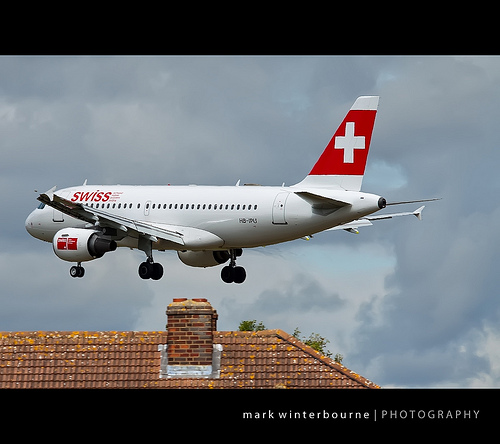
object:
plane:
[25, 95, 442, 282]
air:
[13, 60, 128, 140]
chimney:
[166, 297, 219, 379]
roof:
[1, 330, 382, 389]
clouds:
[0, 56, 499, 388]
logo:
[71, 188, 113, 202]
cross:
[334, 122, 365, 164]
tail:
[293, 95, 378, 192]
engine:
[52, 226, 118, 261]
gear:
[220, 248, 247, 282]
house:
[0, 298, 384, 390]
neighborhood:
[0, 297, 383, 388]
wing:
[294, 190, 351, 206]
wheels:
[138, 262, 152, 281]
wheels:
[219, 265, 238, 284]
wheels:
[68, 266, 81, 278]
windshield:
[37, 200, 45, 209]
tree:
[237, 319, 344, 362]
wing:
[37, 191, 223, 252]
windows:
[146, 203, 149, 208]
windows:
[254, 203, 258, 211]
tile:
[12, 358, 40, 368]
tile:
[54, 366, 78, 374]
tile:
[141, 366, 162, 374]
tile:
[244, 357, 258, 367]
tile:
[308, 371, 325, 378]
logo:
[241, 408, 483, 420]